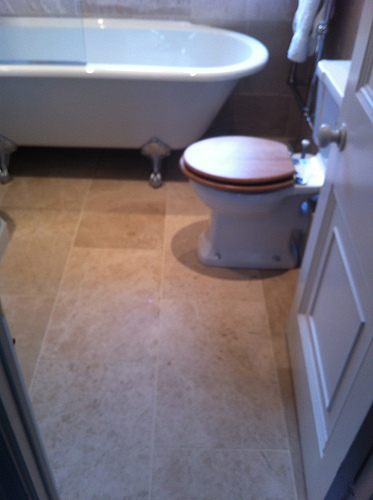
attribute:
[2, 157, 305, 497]
marbled floor — ceramic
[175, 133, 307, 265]
toilet seat — wood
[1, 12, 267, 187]
white tub — porcelain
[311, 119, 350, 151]
white door knob — brown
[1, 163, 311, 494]
colored floor — cream-colored, ceramic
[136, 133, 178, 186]
claw foot — silver, white porcelain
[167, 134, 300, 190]
wooden toilet seat — brown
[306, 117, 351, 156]
silver door knob — metal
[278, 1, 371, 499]
bathroom door — white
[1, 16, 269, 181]
shiny bath tub — large, white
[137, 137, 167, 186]
lion foot — white porcelain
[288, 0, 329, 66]
cotton towel — white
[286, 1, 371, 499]
door with knob — white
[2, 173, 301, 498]
ceramic floor — tan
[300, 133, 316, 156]
toilet plunger — silver 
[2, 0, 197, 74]
shower curtain — clear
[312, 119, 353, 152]
metal door knob — white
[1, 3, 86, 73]
spray shield — glass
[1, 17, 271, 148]
bathtub — white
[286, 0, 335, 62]
towel — white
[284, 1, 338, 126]
rack — silver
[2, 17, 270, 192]
bathtub — white, clawfoot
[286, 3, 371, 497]
door — white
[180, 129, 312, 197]
seat — wooden